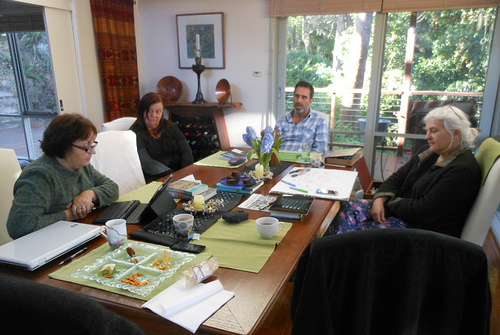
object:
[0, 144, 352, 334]
table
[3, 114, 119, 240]
person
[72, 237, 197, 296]
bowl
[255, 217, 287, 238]
cup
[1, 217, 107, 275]
laptop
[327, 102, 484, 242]
lady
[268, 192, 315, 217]
tablet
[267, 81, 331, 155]
man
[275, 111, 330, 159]
shirt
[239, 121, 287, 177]
plant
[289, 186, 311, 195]
pen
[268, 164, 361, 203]
paper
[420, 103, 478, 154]
hair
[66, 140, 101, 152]
glasses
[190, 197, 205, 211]
candle holder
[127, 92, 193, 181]
woman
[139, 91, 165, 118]
hair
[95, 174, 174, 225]
laptop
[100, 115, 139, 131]
chair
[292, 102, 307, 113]
beard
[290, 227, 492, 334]
jacket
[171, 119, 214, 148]
book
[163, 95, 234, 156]
shelf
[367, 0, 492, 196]
door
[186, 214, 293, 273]
mat